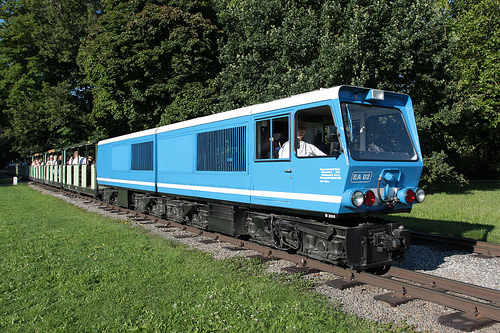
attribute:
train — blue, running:
[1, 83, 426, 271]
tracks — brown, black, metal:
[31, 179, 500, 323]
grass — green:
[0, 177, 427, 333]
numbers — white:
[352, 171, 370, 181]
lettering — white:
[319, 167, 340, 185]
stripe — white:
[97, 177, 342, 205]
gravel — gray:
[392, 244, 499, 299]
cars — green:
[6, 140, 100, 197]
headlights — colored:
[353, 189, 424, 209]